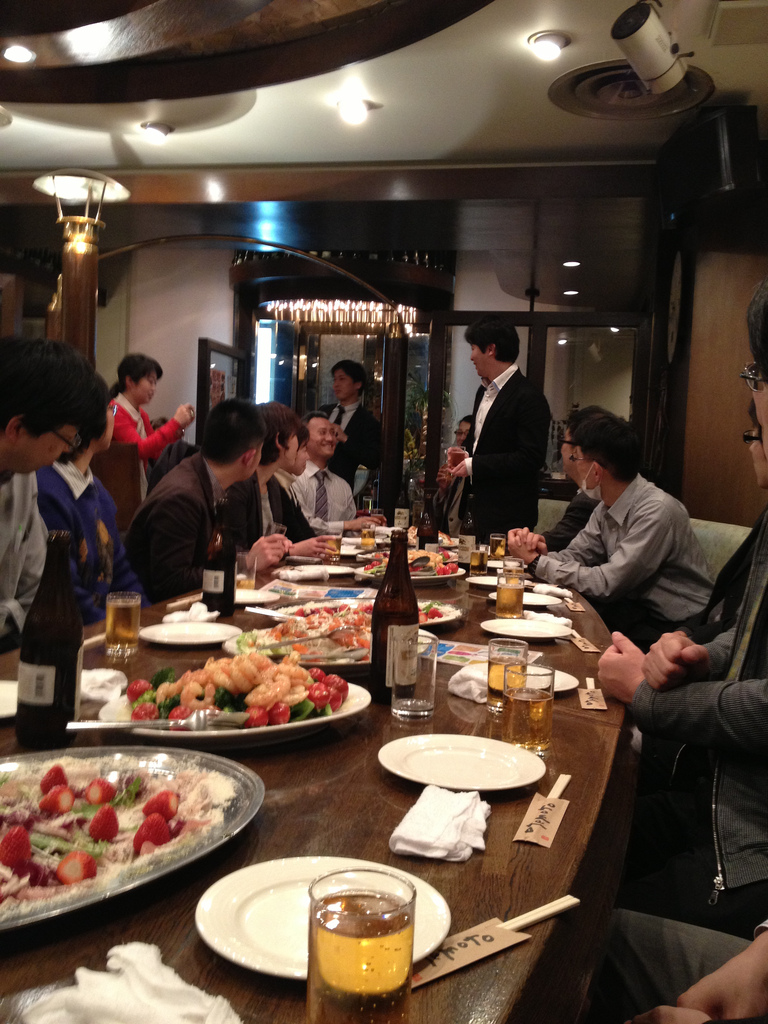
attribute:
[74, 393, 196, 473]
sweater — red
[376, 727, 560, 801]
plate — large, white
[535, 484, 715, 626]
shirt — gray, button down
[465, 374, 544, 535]
jacket — black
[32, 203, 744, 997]
establishment — modern hotel 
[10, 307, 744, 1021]
people — group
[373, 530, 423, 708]
wine — white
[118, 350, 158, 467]
woman — young, in red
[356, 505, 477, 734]
bottles — wine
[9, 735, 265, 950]
tray — full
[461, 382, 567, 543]
suit — black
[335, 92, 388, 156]
lights — white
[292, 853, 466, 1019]
glass — clear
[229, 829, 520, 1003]
plate — white, round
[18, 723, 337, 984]
tray — large, silver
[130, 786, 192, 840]
radishes — red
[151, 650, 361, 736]
shrimp — pink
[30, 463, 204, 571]
shirt — blue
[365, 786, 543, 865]
towel — white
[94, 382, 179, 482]
shirt — white, red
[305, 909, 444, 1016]
liquid — amber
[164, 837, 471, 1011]
plate — white, round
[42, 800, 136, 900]
radishes — red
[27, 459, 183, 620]
shirt — blue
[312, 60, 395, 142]
lights — white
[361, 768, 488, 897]
napkin — white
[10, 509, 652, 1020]
table — dark brown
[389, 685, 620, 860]
plate — white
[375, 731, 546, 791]
plate — white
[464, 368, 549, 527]
suit — black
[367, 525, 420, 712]
bottle — tall, brown, liquor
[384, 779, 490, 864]
napkin — large, white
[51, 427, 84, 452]
eyeglasses — man's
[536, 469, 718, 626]
shirt — man's, gray, dress